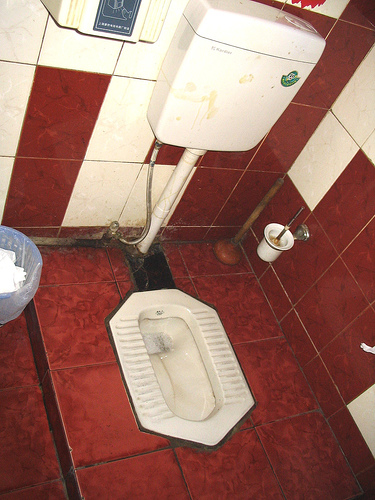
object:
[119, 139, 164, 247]
line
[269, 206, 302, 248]
brush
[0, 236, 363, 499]
floor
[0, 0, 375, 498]
bathroom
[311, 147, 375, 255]
tile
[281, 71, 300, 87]
sticker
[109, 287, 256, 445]
toilet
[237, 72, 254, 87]
stains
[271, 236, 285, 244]
cleaner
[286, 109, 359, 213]
tile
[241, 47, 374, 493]
wall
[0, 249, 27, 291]
tissues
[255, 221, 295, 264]
cleaner container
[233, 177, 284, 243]
wood handle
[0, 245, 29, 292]
garbage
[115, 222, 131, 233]
dust bunnies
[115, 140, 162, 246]
pipes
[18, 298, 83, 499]
step down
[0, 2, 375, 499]
photograph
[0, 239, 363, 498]
ground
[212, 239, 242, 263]
plunger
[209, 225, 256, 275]
bathroom corner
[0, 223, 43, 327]
waste basket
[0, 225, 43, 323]
plastic liner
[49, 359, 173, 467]
tile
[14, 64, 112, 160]
tile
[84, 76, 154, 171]
tile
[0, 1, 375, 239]
wall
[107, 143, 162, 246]
plumbing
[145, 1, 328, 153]
toilet tank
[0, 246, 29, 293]
paper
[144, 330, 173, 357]
water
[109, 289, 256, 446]
toilet bowl